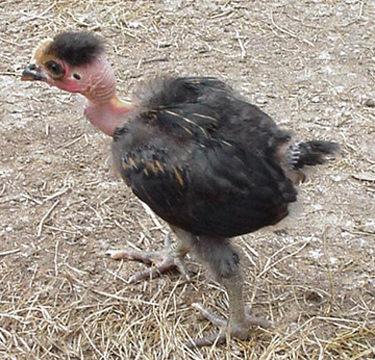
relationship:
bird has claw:
[18, 27, 347, 351] [173, 256, 188, 279]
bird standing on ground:
[18, 27, 347, 351] [0, 4, 372, 356]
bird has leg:
[18, 27, 347, 351] [182, 221, 272, 352]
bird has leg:
[18, 27, 347, 351] [100, 210, 196, 281]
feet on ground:
[187, 302, 272, 350] [0, 4, 372, 356]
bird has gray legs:
[18, 27, 347, 351] [143, 246, 241, 327]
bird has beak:
[18, 27, 347, 351] [20, 60, 45, 81]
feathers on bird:
[121, 73, 334, 234] [18, 27, 347, 351]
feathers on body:
[121, 73, 334, 234] [111, 69, 294, 239]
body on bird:
[111, 69, 294, 239] [18, 27, 347, 351]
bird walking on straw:
[18, 27, 347, 351] [1, 1, 373, 359]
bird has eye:
[18, 27, 347, 351] [42, 60, 69, 82]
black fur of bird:
[113, 74, 310, 240] [18, 27, 347, 351]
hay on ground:
[3, 3, 373, 359] [0, 4, 372, 356]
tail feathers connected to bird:
[289, 133, 344, 176] [18, 27, 347, 351]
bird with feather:
[15, 9, 346, 357] [140, 156, 189, 189]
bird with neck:
[18, 27, 347, 351] [84, 85, 135, 136]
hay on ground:
[3, 3, 373, 359] [117, 1, 373, 82]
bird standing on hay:
[18, 27, 347, 351] [2, 226, 372, 357]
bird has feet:
[18, 27, 347, 351] [118, 243, 274, 344]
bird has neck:
[18, 27, 347, 351] [84, 85, 139, 139]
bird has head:
[18, 27, 347, 351] [21, 19, 131, 108]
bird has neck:
[18, 27, 347, 351] [82, 87, 135, 137]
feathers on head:
[43, 28, 110, 68] [19, 27, 119, 99]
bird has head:
[18, 27, 347, 351] [19, 27, 119, 99]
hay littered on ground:
[3, 3, 373, 359] [5, 42, 357, 348]